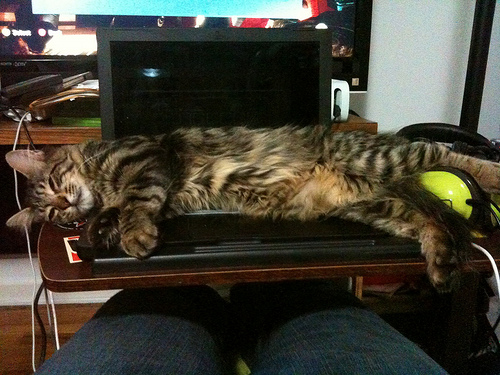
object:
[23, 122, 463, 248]
cat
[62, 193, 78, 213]
nose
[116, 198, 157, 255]
paw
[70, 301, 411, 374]
jeans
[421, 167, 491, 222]
headphones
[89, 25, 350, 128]
laptop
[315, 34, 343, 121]
screen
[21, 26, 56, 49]
tv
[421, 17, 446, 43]
back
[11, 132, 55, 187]
ear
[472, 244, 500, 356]
cable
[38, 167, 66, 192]
eye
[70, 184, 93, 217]
mouth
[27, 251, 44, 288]
wire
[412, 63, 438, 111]
wall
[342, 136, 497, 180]
leg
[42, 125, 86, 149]
shelf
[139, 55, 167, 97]
reflection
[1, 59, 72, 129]
desk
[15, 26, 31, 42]
words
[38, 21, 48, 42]
logos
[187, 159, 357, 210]
belly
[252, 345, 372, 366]
person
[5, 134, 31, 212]
wires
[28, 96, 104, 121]
phone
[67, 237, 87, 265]
paper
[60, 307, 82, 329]
floors